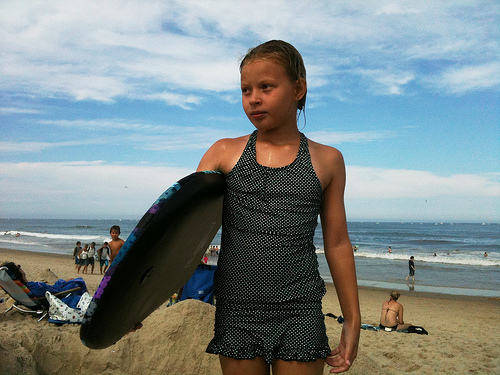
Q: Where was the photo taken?
A: It was taken at the beach.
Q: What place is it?
A: It is a beach.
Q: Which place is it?
A: It is a beach.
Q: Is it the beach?
A: Yes, it is the beach.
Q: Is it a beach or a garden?
A: It is a beach.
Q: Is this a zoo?
A: No, it is a beach.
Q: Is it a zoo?
A: No, it is a beach.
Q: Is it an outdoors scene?
A: Yes, it is outdoors.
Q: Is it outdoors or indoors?
A: It is outdoors.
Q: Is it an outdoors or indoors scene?
A: It is outdoors.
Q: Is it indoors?
A: No, it is outdoors.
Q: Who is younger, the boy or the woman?
A: The boy is younger than the woman.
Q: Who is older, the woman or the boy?
A: The woman is older than the boy.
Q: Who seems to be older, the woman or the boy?
A: The woman is older than the boy.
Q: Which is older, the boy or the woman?
A: The woman is older than the boy.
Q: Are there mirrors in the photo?
A: No, there are no mirrors.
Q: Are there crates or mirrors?
A: No, there are no mirrors or crates.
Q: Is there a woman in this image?
A: Yes, there is a woman.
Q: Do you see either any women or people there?
A: Yes, there is a woman.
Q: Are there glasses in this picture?
A: No, there are no glasses.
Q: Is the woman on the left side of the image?
A: Yes, the woman is on the left of the image.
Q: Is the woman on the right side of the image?
A: No, the woman is on the left of the image.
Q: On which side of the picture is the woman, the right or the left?
A: The woman is on the left of the image.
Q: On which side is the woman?
A: The woman is on the left of the image.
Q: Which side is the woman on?
A: The woman is on the left of the image.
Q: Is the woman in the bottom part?
A: Yes, the woman is in the bottom of the image.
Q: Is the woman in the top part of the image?
A: No, the woman is in the bottom of the image.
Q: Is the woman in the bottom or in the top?
A: The woman is in the bottom of the image.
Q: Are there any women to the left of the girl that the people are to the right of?
A: Yes, there is a woman to the left of the girl.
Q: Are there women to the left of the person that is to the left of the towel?
A: Yes, there is a woman to the left of the girl.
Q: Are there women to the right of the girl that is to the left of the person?
A: No, the woman is to the left of the girl.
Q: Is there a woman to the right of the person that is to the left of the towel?
A: No, the woman is to the left of the girl.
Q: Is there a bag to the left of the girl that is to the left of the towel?
A: No, there is a woman to the left of the girl.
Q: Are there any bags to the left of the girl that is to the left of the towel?
A: No, there is a woman to the left of the girl.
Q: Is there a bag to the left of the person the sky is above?
A: No, there is a woman to the left of the girl.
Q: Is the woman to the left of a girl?
A: Yes, the woman is to the left of a girl.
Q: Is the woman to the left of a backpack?
A: No, the woman is to the left of a girl.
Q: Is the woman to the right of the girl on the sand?
A: No, the woman is to the left of the girl.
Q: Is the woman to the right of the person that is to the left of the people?
A: No, the woman is to the left of the girl.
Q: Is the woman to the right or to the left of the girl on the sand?
A: The woman is to the left of the girl.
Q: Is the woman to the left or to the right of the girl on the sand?
A: The woman is to the left of the girl.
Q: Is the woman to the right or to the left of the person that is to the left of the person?
A: The woman is to the left of the girl.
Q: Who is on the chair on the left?
A: The woman is on the chair.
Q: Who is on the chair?
A: The woman is on the chair.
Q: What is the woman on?
A: The woman is on the chair.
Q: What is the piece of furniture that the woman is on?
A: The piece of furniture is a chair.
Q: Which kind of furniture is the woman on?
A: The woman is on the chair.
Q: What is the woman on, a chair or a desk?
A: The woman is on a chair.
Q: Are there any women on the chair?
A: Yes, there is a woman on the chair.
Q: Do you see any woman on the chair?
A: Yes, there is a woman on the chair.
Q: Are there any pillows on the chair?
A: No, there is a woman on the chair.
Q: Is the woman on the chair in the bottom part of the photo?
A: Yes, the woman is on the chair.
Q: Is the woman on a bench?
A: No, the woman is on the chair.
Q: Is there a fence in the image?
A: No, there are no fences.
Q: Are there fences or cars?
A: No, there are no fences or cars.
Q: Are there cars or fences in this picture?
A: No, there are no fences or cars.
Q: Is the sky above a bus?
A: No, the sky is above a girl.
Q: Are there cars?
A: No, there are no cars.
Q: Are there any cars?
A: No, there are no cars.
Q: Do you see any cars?
A: No, there are no cars.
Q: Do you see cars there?
A: No, there are no cars.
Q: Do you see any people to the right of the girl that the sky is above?
A: Yes, there are people to the right of the girl.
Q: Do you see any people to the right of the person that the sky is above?
A: Yes, there are people to the right of the girl.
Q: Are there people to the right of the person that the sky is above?
A: Yes, there are people to the right of the girl.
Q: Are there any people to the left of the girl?
A: No, the people are to the right of the girl.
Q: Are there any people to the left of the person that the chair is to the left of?
A: No, the people are to the right of the girl.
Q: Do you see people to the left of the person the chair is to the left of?
A: No, the people are to the right of the girl.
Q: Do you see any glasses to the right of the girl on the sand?
A: No, there are people to the right of the girl.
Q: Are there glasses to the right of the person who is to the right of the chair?
A: No, there are people to the right of the girl.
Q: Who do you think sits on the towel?
A: The people sit on the towel.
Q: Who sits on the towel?
A: The people sit on the towel.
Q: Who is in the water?
A: The people are in the water.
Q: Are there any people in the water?
A: Yes, there are people in the water.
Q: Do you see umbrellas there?
A: No, there are no umbrellas.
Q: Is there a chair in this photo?
A: Yes, there is a chair.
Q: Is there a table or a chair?
A: Yes, there is a chair.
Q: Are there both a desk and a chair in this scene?
A: No, there is a chair but no desks.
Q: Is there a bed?
A: No, there are no beds.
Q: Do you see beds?
A: No, there are no beds.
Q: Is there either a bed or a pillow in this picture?
A: No, there are no beds or pillows.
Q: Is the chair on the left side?
A: Yes, the chair is on the left of the image.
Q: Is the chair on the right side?
A: No, the chair is on the left of the image.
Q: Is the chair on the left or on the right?
A: The chair is on the left of the image.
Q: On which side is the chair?
A: The chair is on the left of the image.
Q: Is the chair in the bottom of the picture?
A: Yes, the chair is in the bottom of the image.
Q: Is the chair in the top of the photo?
A: No, the chair is in the bottom of the image.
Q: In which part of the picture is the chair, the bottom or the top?
A: The chair is in the bottom of the image.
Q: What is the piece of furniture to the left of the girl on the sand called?
A: The piece of furniture is a chair.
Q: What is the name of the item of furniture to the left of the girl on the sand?
A: The piece of furniture is a chair.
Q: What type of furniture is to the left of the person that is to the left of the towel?
A: The piece of furniture is a chair.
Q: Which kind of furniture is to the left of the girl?
A: The piece of furniture is a chair.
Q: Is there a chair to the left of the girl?
A: Yes, there is a chair to the left of the girl.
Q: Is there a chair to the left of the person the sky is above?
A: Yes, there is a chair to the left of the girl.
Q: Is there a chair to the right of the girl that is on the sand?
A: No, the chair is to the left of the girl.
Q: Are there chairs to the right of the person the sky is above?
A: No, the chair is to the left of the girl.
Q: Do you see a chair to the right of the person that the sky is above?
A: No, the chair is to the left of the girl.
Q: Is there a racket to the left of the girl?
A: No, there is a chair to the left of the girl.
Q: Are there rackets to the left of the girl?
A: No, there is a chair to the left of the girl.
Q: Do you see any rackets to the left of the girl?
A: No, there is a chair to the left of the girl.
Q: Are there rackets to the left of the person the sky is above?
A: No, there is a chair to the left of the girl.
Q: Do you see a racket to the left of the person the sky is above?
A: No, there is a chair to the left of the girl.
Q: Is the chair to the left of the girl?
A: Yes, the chair is to the left of the girl.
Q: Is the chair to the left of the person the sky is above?
A: Yes, the chair is to the left of the girl.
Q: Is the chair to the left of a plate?
A: No, the chair is to the left of the girl.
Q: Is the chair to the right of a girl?
A: No, the chair is to the left of a girl.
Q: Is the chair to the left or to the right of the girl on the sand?
A: The chair is to the left of the girl.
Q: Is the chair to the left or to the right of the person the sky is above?
A: The chair is to the left of the girl.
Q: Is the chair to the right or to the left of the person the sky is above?
A: The chair is to the left of the girl.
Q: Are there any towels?
A: Yes, there is a towel.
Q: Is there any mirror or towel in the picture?
A: Yes, there is a towel.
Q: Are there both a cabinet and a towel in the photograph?
A: No, there is a towel but no cabinets.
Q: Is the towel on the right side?
A: Yes, the towel is on the right of the image.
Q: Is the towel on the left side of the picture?
A: No, the towel is on the right of the image.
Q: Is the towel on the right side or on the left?
A: The towel is on the right of the image.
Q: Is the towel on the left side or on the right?
A: The towel is on the right of the image.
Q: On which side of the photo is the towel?
A: The towel is on the right of the image.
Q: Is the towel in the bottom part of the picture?
A: Yes, the towel is in the bottom of the image.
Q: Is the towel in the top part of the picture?
A: No, the towel is in the bottom of the image.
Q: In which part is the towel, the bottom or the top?
A: The towel is in the bottom of the image.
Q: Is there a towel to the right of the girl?
A: Yes, there is a towel to the right of the girl.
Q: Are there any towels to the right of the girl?
A: Yes, there is a towel to the right of the girl.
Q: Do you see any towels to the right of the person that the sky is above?
A: Yes, there is a towel to the right of the girl.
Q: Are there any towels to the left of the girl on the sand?
A: No, the towel is to the right of the girl.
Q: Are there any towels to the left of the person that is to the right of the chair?
A: No, the towel is to the right of the girl.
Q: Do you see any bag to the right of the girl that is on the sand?
A: No, there is a towel to the right of the girl.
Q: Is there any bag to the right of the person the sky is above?
A: No, there is a towel to the right of the girl.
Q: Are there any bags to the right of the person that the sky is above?
A: No, there is a towel to the right of the girl.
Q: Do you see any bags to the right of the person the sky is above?
A: No, there is a towel to the right of the girl.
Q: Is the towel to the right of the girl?
A: Yes, the towel is to the right of the girl.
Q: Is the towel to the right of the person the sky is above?
A: Yes, the towel is to the right of the girl.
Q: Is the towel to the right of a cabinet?
A: No, the towel is to the right of the girl.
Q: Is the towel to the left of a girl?
A: No, the towel is to the right of a girl.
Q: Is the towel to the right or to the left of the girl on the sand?
A: The towel is to the right of the girl.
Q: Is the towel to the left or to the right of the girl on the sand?
A: The towel is to the right of the girl.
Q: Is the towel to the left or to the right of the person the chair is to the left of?
A: The towel is to the right of the girl.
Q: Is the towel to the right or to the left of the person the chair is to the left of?
A: The towel is to the right of the girl.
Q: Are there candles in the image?
A: No, there are no candles.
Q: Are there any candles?
A: No, there are no candles.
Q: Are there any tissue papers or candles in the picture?
A: No, there are no candles or tissue papers.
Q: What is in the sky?
A: The clouds are in the sky.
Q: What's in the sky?
A: The clouds are in the sky.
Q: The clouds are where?
A: The clouds are in the sky.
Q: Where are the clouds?
A: The clouds are in the sky.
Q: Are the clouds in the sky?
A: Yes, the clouds are in the sky.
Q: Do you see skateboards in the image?
A: No, there are no skateboards.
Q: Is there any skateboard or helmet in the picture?
A: No, there are no skateboards or helmets.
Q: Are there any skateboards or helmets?
A: No, there are no skateboards or helmets.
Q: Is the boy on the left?
A: Yes, the boy is on the left of the image.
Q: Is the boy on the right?
A: No, the boy is on the left of the image.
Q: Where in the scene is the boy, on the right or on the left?
A: The boy is on the left of the image.